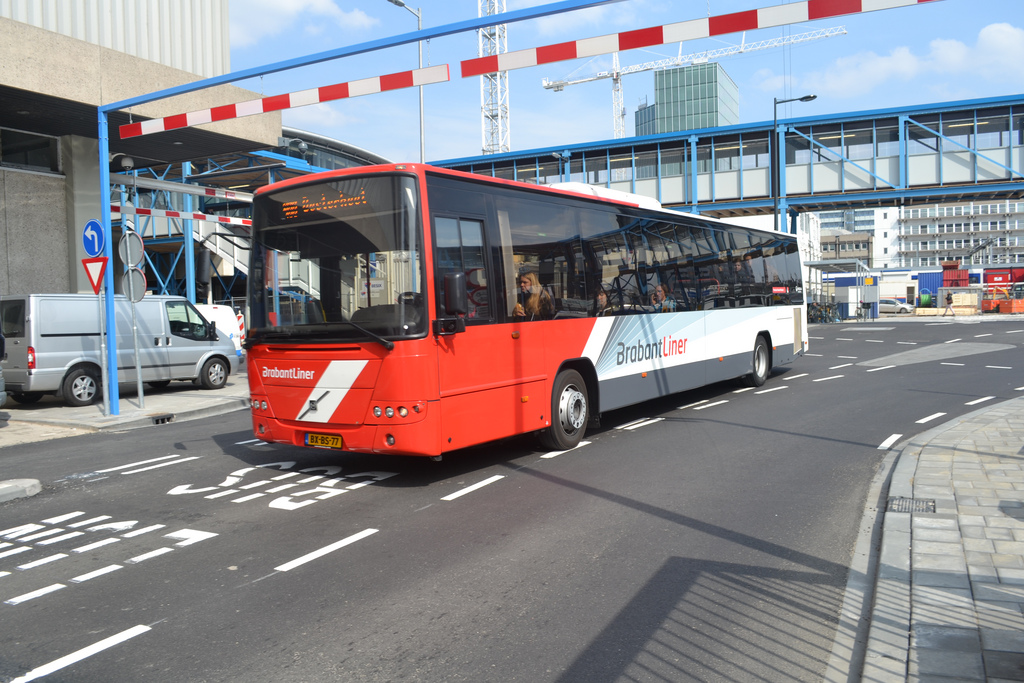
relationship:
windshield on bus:
[248, 175, 433, 332] [239, 175, 805, 461]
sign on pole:
[76, 219, 109, 259] [93, 103, 128, 415]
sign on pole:
[76, 254, 115, 296] [93, 103, 128, 415]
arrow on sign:
[81, 217, 99, 263] [81, 217, 108, 256]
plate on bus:
[302, 432, 341, 449] [239, 175, 805, 461]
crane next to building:
[548, 24, 846, 101] [580, 150, 1021, 308]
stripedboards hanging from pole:
[121, 1, 944, 142] [98, 108, 121, 416]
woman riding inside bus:
[516, 264, 561, 312] [239, 175, 805, 461]